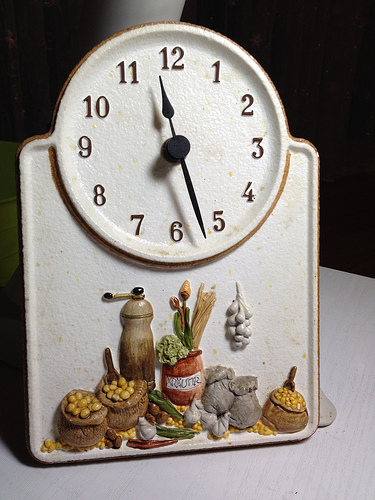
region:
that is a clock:
[21, 30, 317, 446]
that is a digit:
[127, 206, 143, 233]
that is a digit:
[205, 48, 228, 82]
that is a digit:
[244, 132, 269, 160]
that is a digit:
[210, 202, 229, 247]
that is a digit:
[162, 212, 199, 242]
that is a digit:
[84, 180, 108, 205]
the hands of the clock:
[155, 84, 204, 234]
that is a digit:
[71, 133, 92, 160]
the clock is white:
[20, 35, 321, 457]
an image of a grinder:
[101, 287, 156, 389]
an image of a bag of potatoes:
[52, 390, 107, 450]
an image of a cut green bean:
[150, 393, 182, 418]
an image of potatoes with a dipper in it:
[97, 347, 147, 430]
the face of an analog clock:
[50, 21, 290, 270]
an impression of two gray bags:
[204, 365, 263, 428]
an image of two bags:
[201, 365, 263, 430]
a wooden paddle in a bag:
[281, 365, 298, 393]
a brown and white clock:
[51, 20, 291, 269]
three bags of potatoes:
[56, 369, 309, 450]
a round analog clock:
[42, 14, 296, 264]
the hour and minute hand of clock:
[145, 69, 220, 243]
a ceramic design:
[35, 278, 317, 456]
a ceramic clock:
[41, 21, 305, 269]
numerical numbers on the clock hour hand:
[57, 26, 284, 251]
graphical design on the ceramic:
[56, 274, 157, 462]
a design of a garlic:
[223, 278, 256, 352]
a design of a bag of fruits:
[258, 358, 313, 441]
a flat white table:
[322, 279, 372, 321]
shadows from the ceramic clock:
[0, 415, 28, 464]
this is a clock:
[176, 271, 248, 445]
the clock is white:
[75, 242, 195, 290]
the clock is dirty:
[27, 132, 113, 213]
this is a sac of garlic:
[216, 281, 288, 380]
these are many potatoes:
[49, 363, 100, 404]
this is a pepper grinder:
[105, 289, 158, 373]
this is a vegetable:
[151, 336, 198, 361]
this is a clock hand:
[160, 124, 223, 211]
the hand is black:
[166, 209, 202, 236]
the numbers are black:
[156, 182, 204, 257]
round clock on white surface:
[3, 17, 363, 491]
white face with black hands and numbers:
[52, 15, 284, 260]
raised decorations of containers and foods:
[39, 276, 305, 450]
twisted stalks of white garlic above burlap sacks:
[202, 276, 256, 432]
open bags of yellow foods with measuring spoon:
[34, 345, 147, 447]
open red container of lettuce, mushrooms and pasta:
[154, 274, 214, 400]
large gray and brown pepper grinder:
[100, 280, 153, 386]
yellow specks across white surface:
[24, 48, 306, 450]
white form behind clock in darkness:
[4, 1, 368, 276]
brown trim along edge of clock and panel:
[15, 18, 320, 462]